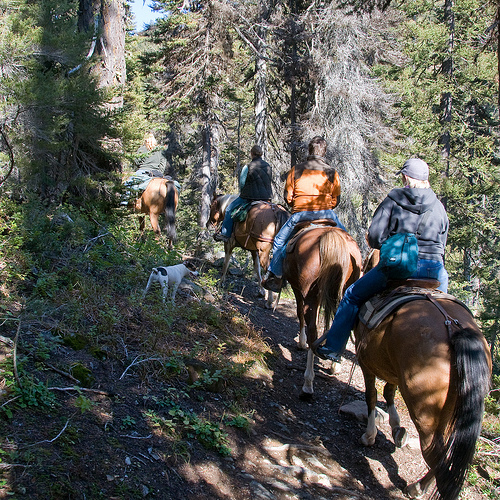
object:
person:
[310, 159, 448, 364]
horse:
[276, 202, 362, 402]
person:
[260, 135, 349, 294]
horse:
[205, 194, 292, 298]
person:
[212, 144, 274, 243]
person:
[115, 132, 167, 212]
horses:
[119, 177, 179, 247]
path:
[160, 232, 402, 499]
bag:
[377, 231, 419, 279]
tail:
[426, 329, 488, 499]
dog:
[141, 260, 199, 307]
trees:
[192, 2, 231, 253]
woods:
[1, 3, 500, 496]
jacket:
[283, 154, 341, 215]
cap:
[395, 157, 431, 180]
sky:
[123, 0, 178, 36]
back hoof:
[392, 427, 409, 449]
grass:
[0, 203, 252, 443]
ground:
[1, 208, 494, 497]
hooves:
[356, 431, 376, 448]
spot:
[153, 267, 168, 276]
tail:
[151, 267, 159, 273]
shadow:
[220, 265, 414, 490]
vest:
[240, 158, 273, 201]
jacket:
[138, 150, 173, 179]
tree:
[69, 0, 129, 221]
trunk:
[251, 38, 271, 149]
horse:
[360, 236, 496, 498]